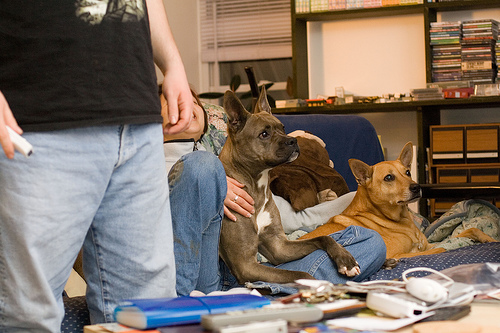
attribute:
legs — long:
[417, 224, 498, 254]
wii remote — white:
[346, 265, 454, 317]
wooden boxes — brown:
[430, 114, 482, 186]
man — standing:
[0, 1, 195, 318]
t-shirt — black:
[3, 0, 177, 128]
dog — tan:
[321, 141, 445, 265]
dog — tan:
[271, 150, 449, 248]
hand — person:
[206, 170, 246, 216]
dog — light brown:
[234, 114, 434, 275]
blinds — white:
[199, 0, 293, 63]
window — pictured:
[200, 5, 297, 100]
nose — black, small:
[410, 183, 421, 193]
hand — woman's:
[225, 181, 253, 222]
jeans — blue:
[16, 108, 145, 329]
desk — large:
[253, 0, 498, 200]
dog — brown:
[237, 94, 297, 201]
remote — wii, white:
[370, 280, 420, 315]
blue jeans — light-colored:
[2, 114, 179, 330]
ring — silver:
[232, 191, 240, 203]